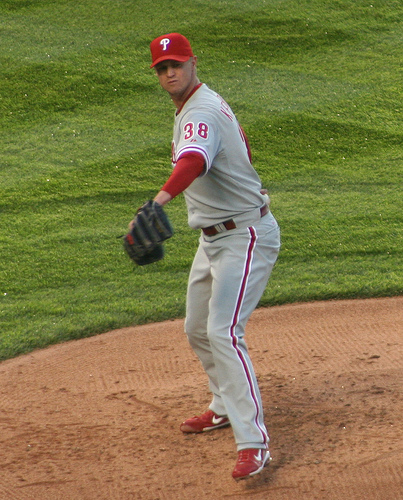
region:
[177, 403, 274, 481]
Red and white Nike branded shoes.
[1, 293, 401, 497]
A red dirt pitcher's mound.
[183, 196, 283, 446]
Baseball uniform pants with a red stripe.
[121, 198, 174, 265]
A black left handed baseball glove.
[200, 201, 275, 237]
A brown man's belt.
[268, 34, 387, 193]
A patch of green in field grass.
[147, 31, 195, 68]
A red baseball cap.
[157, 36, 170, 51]
A P logo on a red hat.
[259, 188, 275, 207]
A baseball about to be thrown.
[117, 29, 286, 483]
A male baseball pitcher.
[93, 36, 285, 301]
this baseball player has on gray and red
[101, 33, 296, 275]
he is prepared to pitch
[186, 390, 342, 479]
he has on red shoes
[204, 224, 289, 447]
he has a red stripe on his pants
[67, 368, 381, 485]
the pitcher's mound is dirty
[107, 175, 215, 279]
the glove is extended outward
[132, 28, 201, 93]
his cap is red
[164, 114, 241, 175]
the jersey number is 38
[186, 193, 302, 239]
he is wearing a belt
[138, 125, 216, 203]
he has on a red shirt under his jersey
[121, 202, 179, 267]
a large black baseball glove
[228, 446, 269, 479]
a man's red tennis shoe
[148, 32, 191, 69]
a red and white baseball cap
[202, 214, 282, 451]
the leg of a man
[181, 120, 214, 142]
a player's team number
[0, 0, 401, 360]
a section of green grass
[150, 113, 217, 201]
the arm of a man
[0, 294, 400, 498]
a brown pitcher's mound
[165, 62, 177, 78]
the nose of a man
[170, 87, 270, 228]
a man's gray jersey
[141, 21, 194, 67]
A red cap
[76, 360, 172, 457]
A dirt track in the photo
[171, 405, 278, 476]
Red shoes in the photo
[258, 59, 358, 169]
Green grass in the photo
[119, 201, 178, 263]
Gloves in the photo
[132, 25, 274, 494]
Baseball player in the photo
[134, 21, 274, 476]
A player on the dirt track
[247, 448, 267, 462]
Nike logo on the shoes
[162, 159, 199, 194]
A red shirt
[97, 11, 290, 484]
a player throwing the ball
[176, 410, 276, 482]
his shoes are red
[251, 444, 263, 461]
a Nike stripe on his shoe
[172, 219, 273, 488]
his pants are grey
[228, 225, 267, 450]
a red stripe on his pants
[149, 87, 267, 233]
his shirt is grey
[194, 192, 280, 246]
his belt is red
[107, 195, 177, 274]
a glove in his hand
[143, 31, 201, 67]
he is wearing a red hat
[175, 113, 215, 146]
the number 38 on his shirt